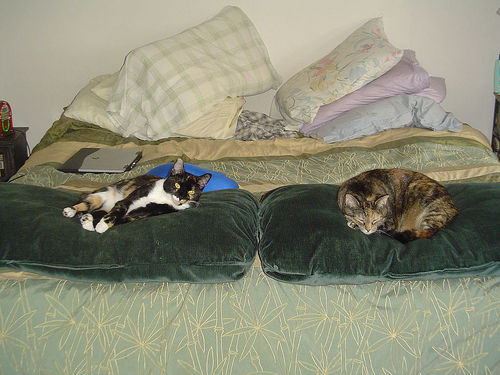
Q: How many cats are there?
A: 2.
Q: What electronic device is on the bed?
A: Laptop.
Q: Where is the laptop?
A: On the bed.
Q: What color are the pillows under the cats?
A: Green.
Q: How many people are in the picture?
A: Zero.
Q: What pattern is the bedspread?
A: Floral.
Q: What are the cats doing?
A: Laying down.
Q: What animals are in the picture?
A: Cats.